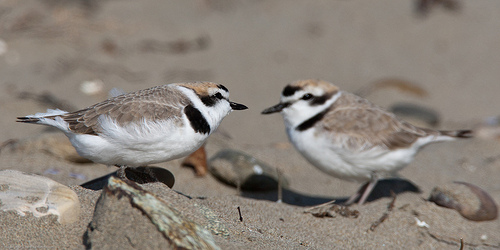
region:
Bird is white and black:
[13, 81, 248, 185]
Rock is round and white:
[1, 168, 80, 229]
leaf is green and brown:
[107, 177, 222, 248]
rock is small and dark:
[208, 146, 293, 199]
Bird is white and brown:
[255, 76, 475, 223]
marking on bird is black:
[182, 101, 214, 138]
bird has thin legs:
[345, 177, 377, 210]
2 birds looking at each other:
[18, 34, 490, 236]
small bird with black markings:
[153, 71, 265, 159]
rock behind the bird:
[421, 170, 495, 225]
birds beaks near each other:
[177, 72, 338, 144]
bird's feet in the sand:
[79, 141, 464, 248]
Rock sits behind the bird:
[0, 160, 89, 231]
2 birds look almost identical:
[22, 45, 497, 231]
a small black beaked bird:
[15, 61, 256, 219]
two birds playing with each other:
[12, 75, 483, 207]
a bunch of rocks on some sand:
[15, 30, 489, 248]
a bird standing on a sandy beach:
[256, 20, 480, 231]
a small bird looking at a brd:
[16, 73, 484, 210]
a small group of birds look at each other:
[16, 73, 480, 213]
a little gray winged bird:
[257, 68, 481, 210]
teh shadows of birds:
[72, 153, 447, 217]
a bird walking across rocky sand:
[13, 25, 251, 195]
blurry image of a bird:
[257, 75, 484, 218]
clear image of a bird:
[14, 75, 251, 199]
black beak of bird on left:
[226, 98, 248, 114]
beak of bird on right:
[258, 101, 284, 123]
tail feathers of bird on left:
[11, 108, 66, 137]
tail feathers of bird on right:
[433, 122, 494, 149]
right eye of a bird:
[213, 90, 222, 100]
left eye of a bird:
[301, 90, 316, 102]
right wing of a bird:
[77, 96, 187, 145]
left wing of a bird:
[314, 103, 424, 168]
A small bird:
[259, 72, 476, 207]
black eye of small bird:
[300, 92, 315, 102]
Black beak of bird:
[259, 99, 293, 115]